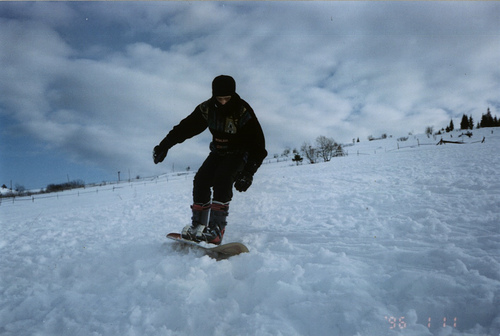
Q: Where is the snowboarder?
A: On the hill.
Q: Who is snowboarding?
A: A person.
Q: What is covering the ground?
A: Snow.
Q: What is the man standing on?
A: Surfboard.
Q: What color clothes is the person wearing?
A: Black.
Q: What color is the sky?
A: Blue.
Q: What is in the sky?
A: Clouds.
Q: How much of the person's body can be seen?
A: Eyes and nose.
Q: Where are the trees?
A: Background.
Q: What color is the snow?
A: White.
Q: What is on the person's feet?
A: Boots.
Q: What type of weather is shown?
A: Cloudy.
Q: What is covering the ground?
A: Snow.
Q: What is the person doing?
A: Snowboarding.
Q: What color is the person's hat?
A: Black.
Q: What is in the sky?
A: Clouds.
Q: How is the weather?
A: It is cold.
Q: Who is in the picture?
A: A boy.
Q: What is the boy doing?
A: Snowboarding.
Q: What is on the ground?
A: Snow.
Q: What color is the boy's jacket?
A: Black.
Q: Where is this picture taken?
A: On a ski slope.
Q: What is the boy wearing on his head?
A: A scarf.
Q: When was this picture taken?
A: Daytime.